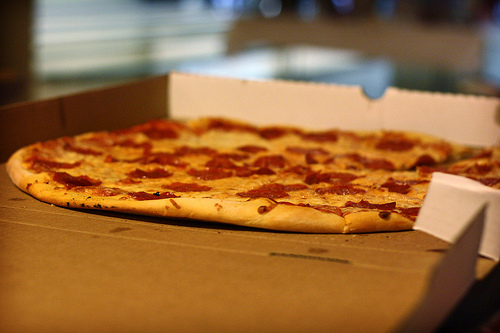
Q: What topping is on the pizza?
A: Pepperoni.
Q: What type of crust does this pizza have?
A: Thin crust.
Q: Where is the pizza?
A: In cardboard box.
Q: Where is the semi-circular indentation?
A: End of cardboard box.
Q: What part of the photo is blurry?
A: Everything behind the box.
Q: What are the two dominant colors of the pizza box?
A: Brown and white.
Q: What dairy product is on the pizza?
A: Cheese.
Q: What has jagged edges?
A: End of cardboard box.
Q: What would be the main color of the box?
A: Tan.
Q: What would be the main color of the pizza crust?
A: Tan.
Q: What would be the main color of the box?
A: Tan.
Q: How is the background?
A: Blurry.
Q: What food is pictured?
A: Pizza.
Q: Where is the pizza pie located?
A: Box.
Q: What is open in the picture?
A: Pizza box.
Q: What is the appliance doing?
A: Reflection light.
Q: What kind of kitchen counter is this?
A: Wooden.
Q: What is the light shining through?
A: Window.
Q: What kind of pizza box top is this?
A: Perforated.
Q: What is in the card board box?
A: Pizza.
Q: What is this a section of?
A: Pizza crust.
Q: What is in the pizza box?
A: Pizza.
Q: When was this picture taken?
A: Daytime.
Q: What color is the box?
A: White and brown.